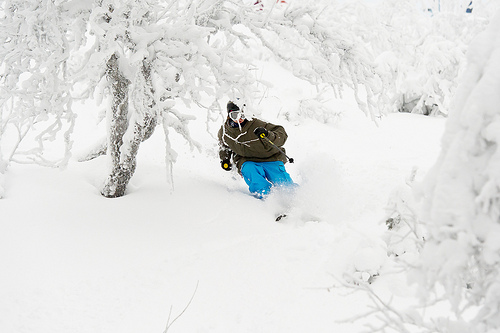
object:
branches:
[153, 51, 218, 110]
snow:
[180, 35, 227, 91]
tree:
[81, 15, 167, 199]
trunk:
[95, 58, 161, 203]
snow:
[0, 184, 346, 333]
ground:
[31, 200, 405, 293]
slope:
[180, 198, 329, 328]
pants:
[242, 159, 295, 203]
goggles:
[229, 111, 246, 120]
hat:
[226, 100, 246, 110]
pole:
[256, 134, 296, 163]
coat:
[217, 119, 287, 164]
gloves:
[253, 125, 267, 138]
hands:
[254, 127, 269, 139]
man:
[221, 99, 308, 222]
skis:
[273, 197, 308, 222]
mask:
[228, 111, 246, 124]